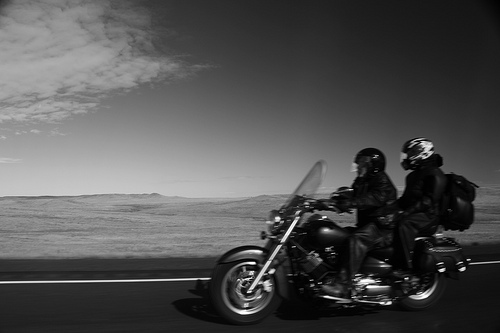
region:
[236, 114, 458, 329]
TWO PEOPLE RIDING ON MOTORCYCLE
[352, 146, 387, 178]
BLACK HELMET ON PERSON'S HEAD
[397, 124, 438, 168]
WHITE HELMET ON PERSON'S HEAD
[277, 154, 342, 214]
SMALL WINDSHIELD ON FRONT OF BIKE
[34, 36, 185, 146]
WHITE CLOUDS IN SKY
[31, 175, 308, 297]
SANDY PLAINS IN BACKGROUND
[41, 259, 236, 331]
BLACK PAVED ROAD UNDER BIKE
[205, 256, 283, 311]
BLACK RUBBER TIRE ON BIKE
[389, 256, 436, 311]
BLACK RUBBER TIRE ON BIKE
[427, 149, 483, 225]
BACKPACK ON BIKE RIDER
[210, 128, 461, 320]
Two people on a motorbike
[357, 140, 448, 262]
they are wearing black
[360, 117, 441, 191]
the are wearing helmets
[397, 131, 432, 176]
This helmet is white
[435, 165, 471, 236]
wearing a large backpack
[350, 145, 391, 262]
He is the driver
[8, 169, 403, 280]
driving near a field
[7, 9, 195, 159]
One large cloud in the sky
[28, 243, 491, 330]
the road is black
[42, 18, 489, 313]
the picture has no color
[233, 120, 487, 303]
Two people on a motorcycle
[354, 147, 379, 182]
person with a black helmet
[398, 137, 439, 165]
person wearing a white helmet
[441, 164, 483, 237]
person wearing a backpack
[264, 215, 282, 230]
headlight on a motorcycle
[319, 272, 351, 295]
person wearing black boots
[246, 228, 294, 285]
chrome pipe on a motorcycle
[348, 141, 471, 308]
Two people on a motorcycle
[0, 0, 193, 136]
The cloud in the sky is white.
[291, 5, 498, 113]
The sky is dark in color.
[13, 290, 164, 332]
The pavement is black.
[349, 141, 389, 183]
The person in the front is wearing a helmet.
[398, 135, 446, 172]
The person in the back is wearing a helmet.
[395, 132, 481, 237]
The person in the back is wearing a back pack.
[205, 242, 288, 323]
The front wheel is black.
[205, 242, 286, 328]
The front wheel is round.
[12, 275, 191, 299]
There is a white stripe on the pavement.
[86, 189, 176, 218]
The mountain in the background is brown.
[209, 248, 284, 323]
Black front wheel on a motorcycle.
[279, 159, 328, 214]
Front windshield of a motorcycle.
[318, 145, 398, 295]
A person driving a motorcycle in a black helmet.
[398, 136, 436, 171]
A white and black helmet on the passenger.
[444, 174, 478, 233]
Large black backpack on the bike passenger.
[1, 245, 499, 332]
A black road with a white line down it.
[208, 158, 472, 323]
A motorcycle with a tall windshield.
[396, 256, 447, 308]
Back black wheel of a bike.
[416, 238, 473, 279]
Black side saddle bag on a bike.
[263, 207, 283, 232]
Front round headlight on a bike.